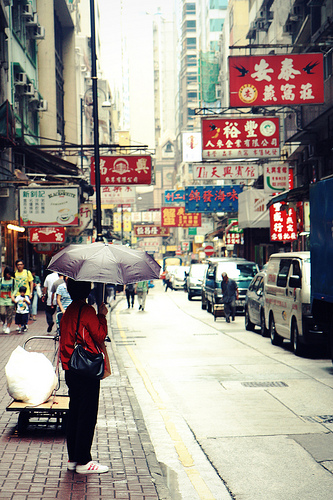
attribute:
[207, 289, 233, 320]
cart — wheeled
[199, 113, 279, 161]
sign — red, white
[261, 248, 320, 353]
van — white, work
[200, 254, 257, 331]
van — white, colored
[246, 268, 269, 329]
car — compact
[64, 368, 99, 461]
pants — black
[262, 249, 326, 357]
van — white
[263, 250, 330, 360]
van — white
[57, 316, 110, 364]
coat — red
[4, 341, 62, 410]
bag — white, large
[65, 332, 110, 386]
bag — white, large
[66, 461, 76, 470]
shoe — white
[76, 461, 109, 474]
shoe — white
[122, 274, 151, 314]
people — headless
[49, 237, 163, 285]
umbrella — dark, opened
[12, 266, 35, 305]
shirt — yellow